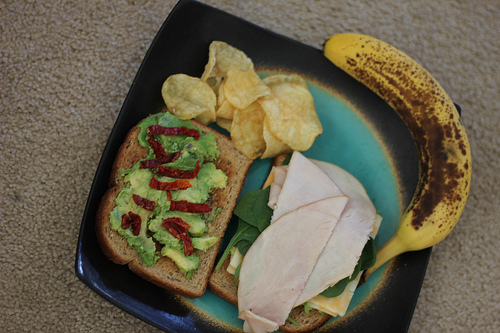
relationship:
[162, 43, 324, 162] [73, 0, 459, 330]
potato chips on plate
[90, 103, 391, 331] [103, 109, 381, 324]
bread has toppings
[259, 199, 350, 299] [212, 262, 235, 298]
turkey meat on bread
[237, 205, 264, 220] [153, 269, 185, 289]
lettuce on bread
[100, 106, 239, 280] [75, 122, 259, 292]
spinach on bread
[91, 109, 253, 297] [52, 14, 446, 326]
bread on plate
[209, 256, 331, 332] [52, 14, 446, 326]
bread on plate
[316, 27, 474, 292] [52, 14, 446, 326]
banana on plate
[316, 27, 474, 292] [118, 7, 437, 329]
banana on plate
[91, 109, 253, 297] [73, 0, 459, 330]
bread on plate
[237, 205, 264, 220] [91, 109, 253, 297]
lettuce on bread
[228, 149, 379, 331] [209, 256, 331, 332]
ham on bread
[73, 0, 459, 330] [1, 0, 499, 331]
plate on carpet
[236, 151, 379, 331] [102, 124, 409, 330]
turkey on sandwich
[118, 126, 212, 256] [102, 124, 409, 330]
topping on sandwich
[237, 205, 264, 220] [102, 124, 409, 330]
lettuce on sandwich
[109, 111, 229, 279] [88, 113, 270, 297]
guacamole on bread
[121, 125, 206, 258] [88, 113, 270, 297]
bacon on bread